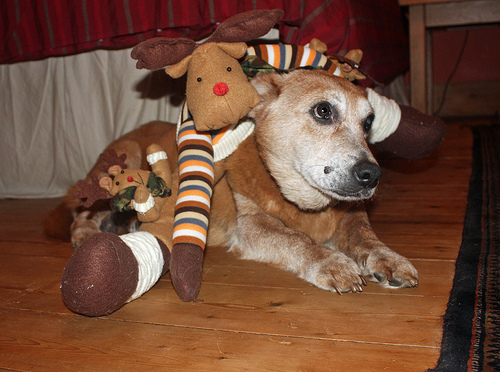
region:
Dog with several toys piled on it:
[43, 21, 424, 315]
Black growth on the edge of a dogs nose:
[317, 163, 337, 175]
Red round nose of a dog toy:
[211, 81, 228, 96]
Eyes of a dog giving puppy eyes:
[309, 98, 380, 131]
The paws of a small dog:
[308, 238, 431, 303]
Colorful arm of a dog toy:
[165, 110, 220, 317]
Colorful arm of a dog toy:
[242, 42, 363, 79]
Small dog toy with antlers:
[60, 148, 171, 220]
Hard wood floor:
[2, 318, 428, 368]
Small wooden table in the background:
[400, 0, 498, 122]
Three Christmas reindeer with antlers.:
[66, 33, 358, 328]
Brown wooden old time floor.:
[18, 87, 464, 359]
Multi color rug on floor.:
[442, 115, 499, 363]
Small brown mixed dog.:
[56, 53, 447, 300]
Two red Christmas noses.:
[121, 68, 249, 193]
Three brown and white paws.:
[52, 205, 439, 299]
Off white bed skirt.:
[8, 50, 233, 197]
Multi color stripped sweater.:
[159, 29, 355, 271]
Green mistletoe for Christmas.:
[111, 173, 175, 215]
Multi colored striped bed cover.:
[12, 7, 372, 67]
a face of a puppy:
[283, 72, 387, 200]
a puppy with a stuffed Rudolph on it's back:
[161, 25, 396, 240]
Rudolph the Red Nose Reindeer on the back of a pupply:
[133, 5, 307, 170]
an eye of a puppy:
[307, 95, 339, 125]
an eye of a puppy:
[360, 100, 378, 134]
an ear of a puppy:
[371, 88, 401, 145]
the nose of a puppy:
[351, 152, 385, 190]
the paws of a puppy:
[306, 240, 418, 297]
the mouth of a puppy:
[311, 186, 385, 204]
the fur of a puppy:
[231, 160, 277, 197]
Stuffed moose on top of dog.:
[135, 4, 428, 281]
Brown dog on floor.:
[61, 52, 421, 293]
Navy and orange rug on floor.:
[437, 122, 498, 370]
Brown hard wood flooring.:
[1, 225, 438, 369]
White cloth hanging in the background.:
[0, 58, 164, 205]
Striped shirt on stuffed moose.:
[135, 27, 351, 291]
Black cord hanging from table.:
[414, 14, 481, 119]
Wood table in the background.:
[390, 2, 490, 142]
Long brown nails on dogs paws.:
[308, 255, 420, 295]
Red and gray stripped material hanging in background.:
[1, 0, 359, 63]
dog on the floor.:
[42, 27, 413, 347]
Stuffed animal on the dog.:
[108, 15, 440, 237]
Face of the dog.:
[266, 44, 416, 219]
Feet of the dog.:
[261, 192, 457, 323]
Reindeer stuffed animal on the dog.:
[138, 19, 371, 296]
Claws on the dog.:
[308, 252, 354, 297]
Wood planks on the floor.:
[181, 268, 317, 355]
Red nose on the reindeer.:
[188, 68, 259, 113]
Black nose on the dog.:
[301, 132, 412, 215]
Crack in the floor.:
[217, 271, 302, 338]